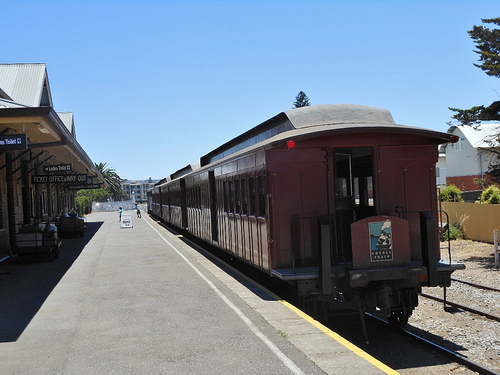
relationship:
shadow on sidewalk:
[0, 208, 98, 343] [72, 195, 249, 374]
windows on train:
[146, 172, 267, 218] [153, 125, 453, 311]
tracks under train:
[387, 292, 498, 358] [153, 125, 453, 311]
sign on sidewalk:
[118, 205, 127, 230] [72, 195, 249, 374]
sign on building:
[31, 161, 80, 182] [12, 76, 105, 268]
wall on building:
[0, 164, 33, 232] [12, 76, 105, 268]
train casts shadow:
[153, 125, 453, 311] [157, 215, 284, 298]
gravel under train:
[413, 303, 493, 330] [153, 125, 453, 311]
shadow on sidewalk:
[157, 215, 284, 298] [72, 195, 249, 374]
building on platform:
[12, 76, 105, 268] [4, 71, 343, 370]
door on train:
[338, 149, 382, 271] [153, 125, 453, 311]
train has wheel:
[153, 125, 453, 311] [384, 293, 406, 330]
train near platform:
[153, 125, 453, 311] [4, 71, 343, 370]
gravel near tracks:
[413, 303, 493, 330] [387, 292, 498, 358]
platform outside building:
[4, 71, 343, 370] [12, 76, 105, 268]